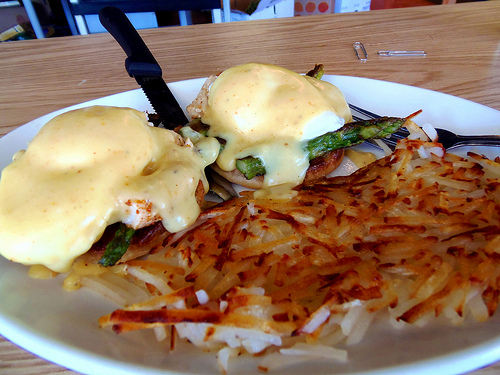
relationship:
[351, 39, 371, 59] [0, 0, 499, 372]
paperclip on table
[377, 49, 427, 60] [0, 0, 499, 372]
paperclip on table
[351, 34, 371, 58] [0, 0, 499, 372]
paperclip on table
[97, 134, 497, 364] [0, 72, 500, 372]
hashbrowns on plate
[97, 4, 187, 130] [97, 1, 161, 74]
knife has handle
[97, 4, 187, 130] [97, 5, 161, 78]
knife has handle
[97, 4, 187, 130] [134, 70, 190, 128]
knife has blade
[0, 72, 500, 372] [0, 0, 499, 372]
plate on table